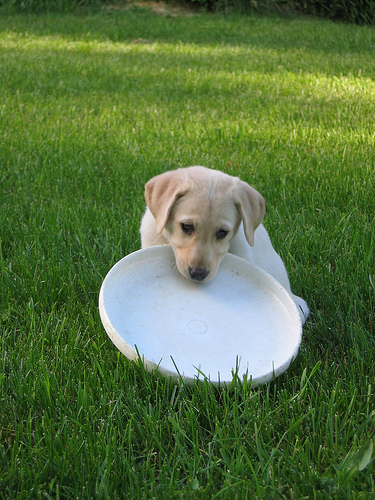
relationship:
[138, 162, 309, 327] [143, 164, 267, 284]
dog has head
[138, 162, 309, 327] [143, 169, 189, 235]
dog has ear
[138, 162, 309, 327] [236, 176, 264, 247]
dog has ear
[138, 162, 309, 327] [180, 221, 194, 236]
dog has eye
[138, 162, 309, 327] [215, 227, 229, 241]
dog has eye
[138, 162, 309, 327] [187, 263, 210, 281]
dog has nose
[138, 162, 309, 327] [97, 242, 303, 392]
dog holds frisbee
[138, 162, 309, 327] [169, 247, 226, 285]
dog has mouth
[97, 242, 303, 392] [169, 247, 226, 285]
frisbee in mouth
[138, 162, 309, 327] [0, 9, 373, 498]
dog on top of grass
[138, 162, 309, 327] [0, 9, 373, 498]
dog in park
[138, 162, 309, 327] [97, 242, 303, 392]
dog has frisbee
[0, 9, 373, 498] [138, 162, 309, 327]
grass surrounds dog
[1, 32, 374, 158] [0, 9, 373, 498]
light shines on grass